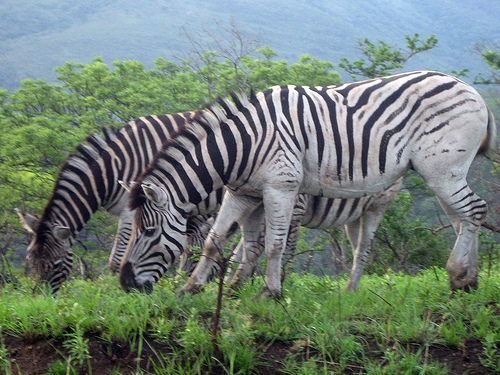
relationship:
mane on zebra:
[35, 120, 108, 242] [27, 68, 351, 309]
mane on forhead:
[120, 90, 279, 230] [124, 168, 205, 292]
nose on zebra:
[104, 254, 164, 305] [102, 48, 465, 310]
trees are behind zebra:
[3, 10, 484, 103] [36, 49, 476, 305]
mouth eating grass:
[115, 258, 183, 300] [7, 249, 469, 368]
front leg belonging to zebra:
[176, 188, 263, 295] [116, 62, 485, 303]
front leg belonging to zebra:
[260, 160, 303, 303] [116, 62, 485, 303]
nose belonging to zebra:
[119, 277, 133, 293] [116, 62, 485, 303]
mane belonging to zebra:
[35, 120, 108, 242] [11, 107, 226, 299]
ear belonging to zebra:
[11, 207, 41, 235] [11, 107, 226, 299]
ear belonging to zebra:
[50, 223, 73, 241] [11, 107, 226, 299]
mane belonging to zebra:
[34, 120, 123, 260] [11, 107, 226, 299]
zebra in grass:
[33, 59, 481, 324] [248, 295, 312, 339]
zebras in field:
[74, 58, 416, 259] [108, 233, 417, 351]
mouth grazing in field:
[139, 282, 152, 295] [3, 270, 496, 371]